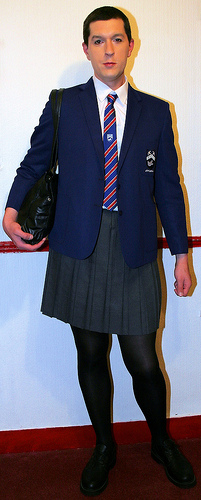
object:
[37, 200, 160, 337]
skirt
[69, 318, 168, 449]
tights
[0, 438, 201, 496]
floor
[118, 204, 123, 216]
buttons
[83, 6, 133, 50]
hair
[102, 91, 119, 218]
tie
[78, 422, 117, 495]
black shoes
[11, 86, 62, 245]
black purse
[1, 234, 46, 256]
crown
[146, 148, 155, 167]
emblem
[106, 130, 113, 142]
emblem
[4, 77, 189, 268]
jacket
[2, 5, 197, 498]
man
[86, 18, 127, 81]
makeup